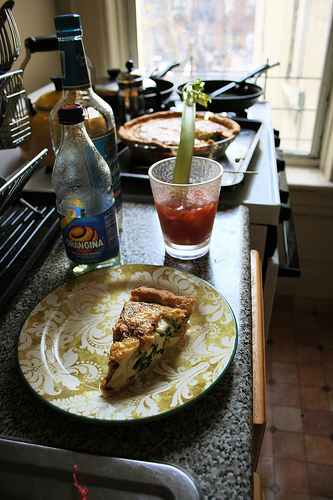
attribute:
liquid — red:
[155, 194, 218, 244]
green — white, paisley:
[19, 266, 235, 421]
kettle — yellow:
[22, 38, 111, 157]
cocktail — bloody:
[143, 77, 221, 259]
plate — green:
[13, 259, 244, 428]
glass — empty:
[147, 156, 222, 260]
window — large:
[135, 0, 331, 154]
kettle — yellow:
[20, 33, 110, 162]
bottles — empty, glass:
[42, 6, 128, 269]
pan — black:
[157, 68, 286, 120]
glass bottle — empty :
[34, 121, 131, 276]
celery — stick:
[165, 86, 200, 208]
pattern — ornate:
[17, 264, 237, 420]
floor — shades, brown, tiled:
[260, 288, 332, 498]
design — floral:
[17, 263, 237, 422]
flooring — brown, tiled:
[259, 293, 331, 498]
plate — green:
[18, 263, 237, 420]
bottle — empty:
[51, 104, 121, 272]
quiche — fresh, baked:
[97, 286, 193, 390]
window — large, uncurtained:
[138, 30, 317, 164]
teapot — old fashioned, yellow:
[6, 30, 102, 155]